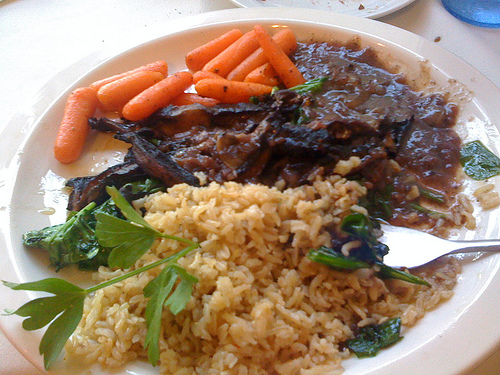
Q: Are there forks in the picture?
A: Yes, there is a fork.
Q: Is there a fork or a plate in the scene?
A: Yes, there is a fork.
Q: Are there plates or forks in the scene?
A: Yes, there is a fork.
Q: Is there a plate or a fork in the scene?
A: Yes, there is a fork.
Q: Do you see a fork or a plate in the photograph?
A: Yes, there is a fork.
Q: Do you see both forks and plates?
A: Yes, there are both a fork and a plate.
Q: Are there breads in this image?
A: No, there are no breads.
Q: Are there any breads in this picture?
A: No, there are no breads.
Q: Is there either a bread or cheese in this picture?
A: No, there are no breads or cheese.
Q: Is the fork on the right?
A: Yes, the fork is on the right of the image.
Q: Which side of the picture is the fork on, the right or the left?
A: The fork is on the right of the image.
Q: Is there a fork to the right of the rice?
A: Yes, there is a fork to the right of the rice.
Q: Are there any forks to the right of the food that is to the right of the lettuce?
A: Yes, there is a fork to the right of the rice.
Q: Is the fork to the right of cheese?
A: No, the fork is to the right of the rice.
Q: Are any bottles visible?
A: No, there are no bottles.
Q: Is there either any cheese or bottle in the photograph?
A: No, there are no bottles or cheese.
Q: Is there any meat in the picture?
A: Yes, there is meat.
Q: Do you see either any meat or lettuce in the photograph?
A: Yes, there is meat.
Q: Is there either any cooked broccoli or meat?
A: Yes, there is cooked meat.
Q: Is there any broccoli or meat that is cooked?
A: Yes, the meat is cooked.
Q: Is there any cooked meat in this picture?
A: Yes, there is cooked meat.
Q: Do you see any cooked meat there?
A: Yes, there is cooked meat.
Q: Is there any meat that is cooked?
A: Yes, there is meat that is cooked.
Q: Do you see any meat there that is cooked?
A: Yes, there is meat that is cooked.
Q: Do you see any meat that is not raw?
A: Yes, there is cooked meat.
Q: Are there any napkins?
A: No, there are no napkins.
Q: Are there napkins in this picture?
A: No, there are no napkins.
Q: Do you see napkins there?
A: No, there are no napkins.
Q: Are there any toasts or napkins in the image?
A: No, there are no napkins or toasts.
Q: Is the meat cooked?
A: Yes, the meat is cooked.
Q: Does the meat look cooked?
A: Yes, the meat is cooked.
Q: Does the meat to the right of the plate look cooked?
A: Yes, the meat is cooked.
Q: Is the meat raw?
A: No, the meat is cooked.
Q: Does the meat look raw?
A: No, the meat is cooked.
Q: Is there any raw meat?
A: No, there is meat but it is cooked.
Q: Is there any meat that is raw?
A: No, there is meat but it is cooked.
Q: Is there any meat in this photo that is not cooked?
A: No, there is meat but it is cooked.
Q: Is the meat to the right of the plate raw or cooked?
A: The meat is cooked.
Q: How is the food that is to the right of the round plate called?
A: The food is meat.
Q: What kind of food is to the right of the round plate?
A: The food is meat.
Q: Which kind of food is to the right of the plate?
A: The food is meat.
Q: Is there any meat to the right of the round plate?
A: Yes, there is meat to the right of the plate.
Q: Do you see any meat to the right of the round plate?
A: Yes, there is meat to the right of the plate.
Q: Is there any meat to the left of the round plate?
A: No, the meat is to the right of the plate.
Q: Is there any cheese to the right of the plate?
A: No, there is meat to the right of the plate.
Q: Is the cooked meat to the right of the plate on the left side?
A: Yes, the meat is to the right of the plate.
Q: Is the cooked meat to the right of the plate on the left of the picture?
A: Yes, the meat is to the right of the plate.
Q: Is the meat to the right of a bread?
A: No, the meat is to the right of the plate.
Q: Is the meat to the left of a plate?
A: No, the meat is to the right of a plate.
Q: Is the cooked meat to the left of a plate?
A: No, the meat is to the right of a plate.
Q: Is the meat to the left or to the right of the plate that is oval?
A: The meat is to the right of the plate.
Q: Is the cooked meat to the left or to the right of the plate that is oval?
A: The meat is to the right of the plate.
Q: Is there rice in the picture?
A: Yes, there is rice.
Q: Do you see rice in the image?
A: Yes, there is rice.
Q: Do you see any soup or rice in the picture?
A: Yes, there is rice.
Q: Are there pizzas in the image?
A: No, there are no pizzas.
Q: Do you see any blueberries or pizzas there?
A: No, there are no pizzas or blueberries.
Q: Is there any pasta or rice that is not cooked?
A: No, there is rice but it is cooked.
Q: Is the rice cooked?
A: Yes, the rice is cooked.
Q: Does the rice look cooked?
A: Yes, the rice is cooked.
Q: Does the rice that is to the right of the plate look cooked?
A: Yes, the rice is cooked.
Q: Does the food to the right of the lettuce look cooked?
A: Yes, the rice is cooked.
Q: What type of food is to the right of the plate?
A: The food is rice.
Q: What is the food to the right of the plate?
A: The food is rice.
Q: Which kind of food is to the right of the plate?
A: The food is rice.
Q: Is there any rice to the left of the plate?
A: No, the rice is to the right of the plate.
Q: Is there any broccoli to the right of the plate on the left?
A: No, there is rice to the right of the plate.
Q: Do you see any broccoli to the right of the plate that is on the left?
A: No, there is rice to the right of the plate.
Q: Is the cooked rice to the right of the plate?
A: Yes, the rice is to the right of the plate.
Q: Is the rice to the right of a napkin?
A: No, the rice is to the right of the plate.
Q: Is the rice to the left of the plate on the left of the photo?
A: No, the rice is to the right of the plate.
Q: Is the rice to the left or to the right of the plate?
A: The rice is to the right of the plate.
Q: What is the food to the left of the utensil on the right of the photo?
A: The food is rice.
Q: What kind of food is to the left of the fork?
A: The food is rice.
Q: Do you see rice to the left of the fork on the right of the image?
A: Yes, there is rice to the left of the fork.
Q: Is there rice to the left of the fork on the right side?
A: Yes, there is rice to the left of the fork.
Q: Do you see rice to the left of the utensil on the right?
A: Yes, there is rice to the left of the fork.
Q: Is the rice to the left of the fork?
A: Yes, the rice is to the left of the fork.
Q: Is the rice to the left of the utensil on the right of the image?
A: Yes, the rice is to the left of the fork.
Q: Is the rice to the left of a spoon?
A: No, the rice is to the left of the fork.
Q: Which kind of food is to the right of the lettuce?
A: The food is rice.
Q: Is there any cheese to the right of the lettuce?
A: No, there is rice to the right of the lettuce.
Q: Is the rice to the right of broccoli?
A: No, the rice is to the right of the lettuce.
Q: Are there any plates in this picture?
A: Yes, there is a plate.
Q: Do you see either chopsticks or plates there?
A: Yes, there is a plate.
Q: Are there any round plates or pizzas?
A: Yes, there is a round plate.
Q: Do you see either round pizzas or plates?
A: Yes, there is a round plate.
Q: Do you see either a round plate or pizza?
A: Yes, there is a round plate.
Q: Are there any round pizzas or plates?
A: Yes, there is a round plate.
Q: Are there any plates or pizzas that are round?
A: Yes, the plate is round.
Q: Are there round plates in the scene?
A: Yes, there is a round plate.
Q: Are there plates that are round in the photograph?
A: Yes, there is a round plate.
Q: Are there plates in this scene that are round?
A: Yes, there is a plate that is round.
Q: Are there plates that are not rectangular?
A: Yes, there is a round plate.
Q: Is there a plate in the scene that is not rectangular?
A: Yes, there is a round plate.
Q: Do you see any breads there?
A: No, there are no breads.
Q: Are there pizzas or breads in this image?
A: No, there are no breads or pizzas.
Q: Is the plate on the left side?
A: Yes, the plate is on the left of the image.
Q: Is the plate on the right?
A: No, the plate is on the left of the image.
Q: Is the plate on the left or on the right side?
A: The plate is on the left of the image.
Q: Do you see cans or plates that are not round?
A: No, there is a plate but it is round.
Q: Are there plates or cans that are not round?
A: No, there is a plate but it is round.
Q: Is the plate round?
A: Yes, the plate is round.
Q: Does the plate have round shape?
A: Yes, the plate is round.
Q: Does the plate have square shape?
A: No, the plate is round.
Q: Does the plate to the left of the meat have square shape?
A: No, the plate is round.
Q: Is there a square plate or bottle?
A: No, there is a plate but it is round.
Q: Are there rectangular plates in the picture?
A: No, there is a plate but it is round.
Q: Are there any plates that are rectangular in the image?
A: No, there is a plate but it is round.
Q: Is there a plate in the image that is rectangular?
A: No, there is a plate but it is round.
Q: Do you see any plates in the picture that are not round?
A: No, there is a plate but it is round.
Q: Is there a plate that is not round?
A: No, there is a plate but it is round.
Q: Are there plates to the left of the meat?
A: Yes, there is a plate to the left of the meat.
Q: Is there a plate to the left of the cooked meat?
A: Yes, there is a plate to the left of the meat.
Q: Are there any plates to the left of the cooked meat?
A: Yes, there is a plate to the left of the meat.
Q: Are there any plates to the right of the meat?
A: No, the plate is to the left of the meat.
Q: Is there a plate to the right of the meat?
A: No, the plate is to the left of the meat.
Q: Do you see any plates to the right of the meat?
A: No, the plate is to the left of the meat.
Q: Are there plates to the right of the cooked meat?
A: No, the plate is to the left of the meat.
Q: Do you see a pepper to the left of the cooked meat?
A: No, there is a plate to the left of the meat.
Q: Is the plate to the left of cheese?
A: No, the plate is to the left of the meat.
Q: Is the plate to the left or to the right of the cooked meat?
A: The plate is to the left of the meat.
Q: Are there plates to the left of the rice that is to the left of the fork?
A: Yes, there is a plate to the left of the rice.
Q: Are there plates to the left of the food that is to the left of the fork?
A: Yes, there is a plate to the left of the rice.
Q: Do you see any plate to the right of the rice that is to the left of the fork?
A: No, the plate is to the left of the rice.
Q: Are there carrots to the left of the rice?
A: No, there is a plate to the left of the rice.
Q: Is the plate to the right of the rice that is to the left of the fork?
A: No, the plate is to the left of the rice.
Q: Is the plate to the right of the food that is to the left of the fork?
A: No, the plate is to the left of the rice.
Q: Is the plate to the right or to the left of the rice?
A: The plate is to the left of the rice.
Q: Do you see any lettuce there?
A: Yes, there is lettuce.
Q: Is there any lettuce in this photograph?
A: Yes, there is lettuce.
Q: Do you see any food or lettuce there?
A: Yes, there is lettuce.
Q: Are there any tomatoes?
A: No, there are no tomatoes.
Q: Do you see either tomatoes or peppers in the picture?
A: No, there are no tomatoes or peppers.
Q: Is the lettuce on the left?
A: Yes, the lettuce is on the left of the image.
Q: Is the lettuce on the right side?
A: No, the lettuce is on the left of the image.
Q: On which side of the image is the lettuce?
A: The lettuce is on the left of the image.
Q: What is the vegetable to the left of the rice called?
A: The vegetable is lettuce.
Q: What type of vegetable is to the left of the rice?
A: The vegetable is lettuce.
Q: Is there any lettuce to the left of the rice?
A: Yes, there is lettuce to the left of the rice.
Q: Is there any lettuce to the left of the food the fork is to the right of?
A: Yes, there is lettuce to the left of the rice.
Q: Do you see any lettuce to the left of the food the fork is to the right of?
A: Yes, there is lettuce to the left of the rice.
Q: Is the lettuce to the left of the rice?
A: Yes, the lettuce is to the left of the rice.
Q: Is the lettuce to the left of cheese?
A: No, the lettuce is to the left of the rice.